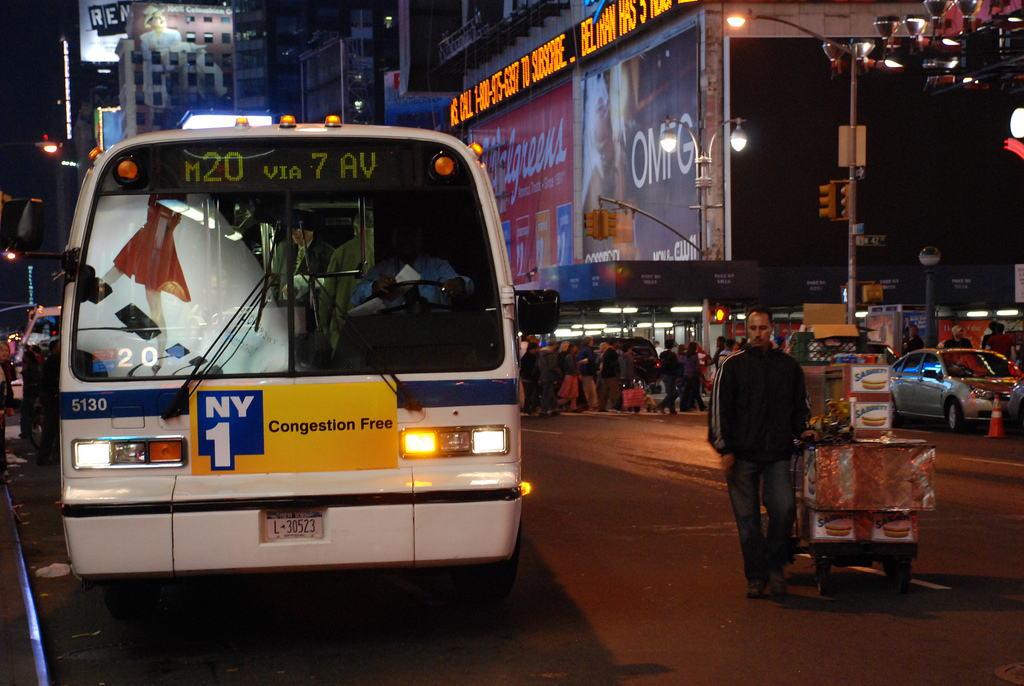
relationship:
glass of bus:
[45, 152, 629, 418] [60, 106, 573, 636]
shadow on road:
[449, 565, 640, 667] [507, 381, 853, 678]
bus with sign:
[54, 91, 668, 656] [196, 359, 423, 472]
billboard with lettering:
[429, 55, 680, 256] [484, 81, 603, 341]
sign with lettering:
[108, 323, 480, 490] [233, 392, 365, 470]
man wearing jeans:
[687, 273, 824, 621] [713, 456, 832, 597]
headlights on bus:
[65, 398, 625, 498] [19, 70, 711, 595]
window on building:
[840, 87, 877, 196] [566, 59, 990, 505]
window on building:
[793, 55, 867, 136] [484, 57, 921, 477]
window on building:
[831, 197, 989, 347] [486, 59, 958, 487]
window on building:
[559, 238, 672, 334] [449, 61, 979, 485]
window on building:
[836, 44, 958, 230] [479, 44, 938, 429]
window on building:
[877, 137, 955, 243] [447, 70, 906, 451]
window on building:
[775, 50, 830, 198] [430, 27, 953, 477]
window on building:
[747, 44, 825, 179] [449, 61, 979, 485]